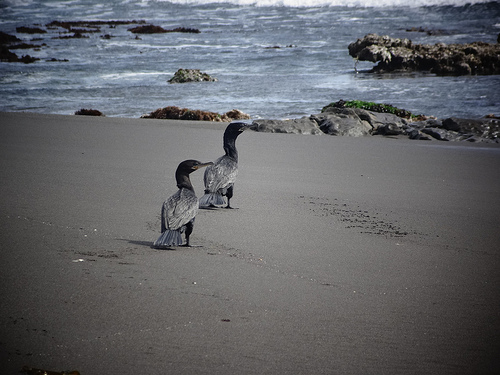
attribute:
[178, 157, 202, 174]
head — curved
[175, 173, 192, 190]
neck — curved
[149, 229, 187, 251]
tail — straight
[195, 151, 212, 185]
narrow beak — pointed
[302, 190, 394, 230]
sand — gray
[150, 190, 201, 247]
back — oval shaped